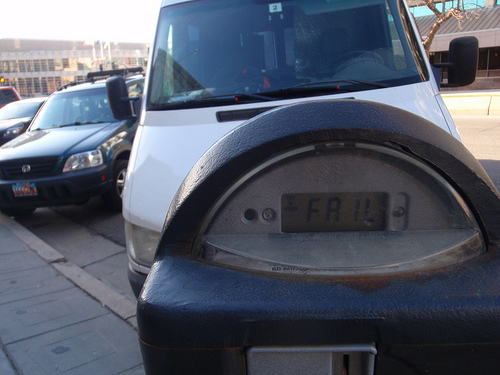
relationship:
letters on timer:
[307, 195, 378, 223] [283, 189, 392, 231]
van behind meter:
[126, 0, 481, 285] [134, 95, 499, 368]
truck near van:
[2, 71, 143, 231] [119, 2, 467, 297]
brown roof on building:
[413, 13, 497, 33] [414, 16, 494, 112]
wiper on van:
[235, 95, 335, 100] [119, 2, 467, 297]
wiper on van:
[259, 84, 341, 94] [119, 2, 467, 297]